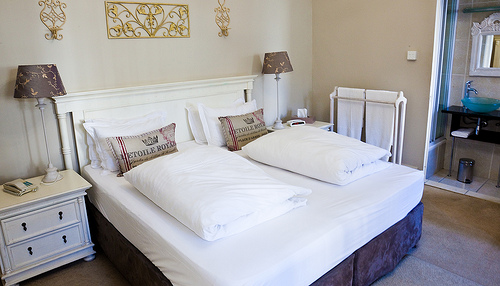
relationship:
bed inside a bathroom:
[84, 131, 428, 286] [0, 0, 499, 286]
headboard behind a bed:
[46, 78, 256, 160] [84, 131, 428, 286]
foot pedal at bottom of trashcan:
[465, 179, 469, 183] [456, 158, 476, 188]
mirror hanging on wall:
[469, 14, 500, 78] [449, 4, 499, 174]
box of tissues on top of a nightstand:
[294, 109, 316, 122] [268, 117, 336, 134]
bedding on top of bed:
[132, 145, 298, 240] [84, 131, 428, 286]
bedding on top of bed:
[245, 127, 391, 187] [84, 131, 428, 286]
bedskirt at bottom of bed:
[311, 208, 421, 286] [84, 131, 428, 286]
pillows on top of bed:
[179, 101, 262, 141] [84, 131, 428, 286]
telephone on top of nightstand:
[3, 178, 41, 200] [3, 173, 93, 286]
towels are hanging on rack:
[338, 81, 394, 144] [327, 85, 404, 178]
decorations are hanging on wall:
[36, 1, 238, 45] [1, 2, 308, 174]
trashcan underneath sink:
[456, 158, 476, 188] [442, 82, 499, 152]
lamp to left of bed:
[11, 63, 78, 191] [84, 131, 428, 286]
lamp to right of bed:
[258, 51, 296, 131] [84, 131, 428, 286]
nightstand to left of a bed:
[3, 173, 93, 286] [84, 131, 428, 286]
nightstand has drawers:
[3, 173, 93, 286] [2, 211, 88, 256]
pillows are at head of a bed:
[179, 101, 262, 141] [84, 131, 428, 286]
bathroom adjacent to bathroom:
[432, 7, 499, 194] [0, 0, 499, 286]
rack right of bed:
[327, 85, 404, 178] [84, 131, 428, 286]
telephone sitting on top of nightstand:
[3, 178, 41, 200] [3, 173, 93, 286]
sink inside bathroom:
[442, 82, 499, 152] [432, 7, 499, 194]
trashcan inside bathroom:
[456, 158, 476, 188] [432, 7, 499, 194]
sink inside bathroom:
[460, 96, 500, 112] [432, 7, 499, 194]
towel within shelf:
[447, 124, 476, 143] [449, 115, 499, 142]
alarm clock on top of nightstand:
[284, 118, 306, 129] [268, 117, 336, 134]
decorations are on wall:
[36, 1, 238, 45] [1, 2, 308, 174]